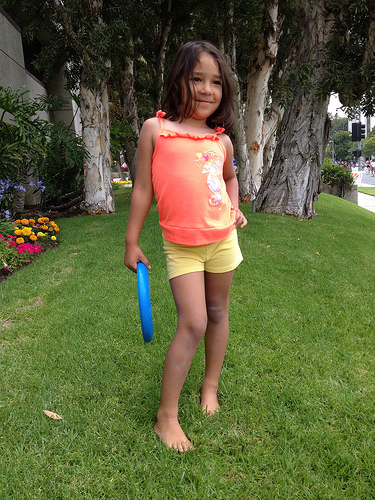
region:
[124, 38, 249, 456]
a young girl in shorts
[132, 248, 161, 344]
a blue Frisbee in right hand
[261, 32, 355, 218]
gray and black tree trunk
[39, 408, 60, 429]
die leaf on the ground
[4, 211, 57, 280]
a bed of flowers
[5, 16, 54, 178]
a concrete building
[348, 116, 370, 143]
a stop light over the street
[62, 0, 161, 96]
brushy green tree limbs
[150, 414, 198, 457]
toes on a foot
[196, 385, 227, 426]
grass around foot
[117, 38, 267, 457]
little girl posing for photo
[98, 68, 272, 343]
little girl holding a blue frisbee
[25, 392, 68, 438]
one leave on top of green grass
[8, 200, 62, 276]
pink and yellow flowers in a flower bed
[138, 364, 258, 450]
little girl wearing no shoes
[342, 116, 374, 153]
black stree light in the distance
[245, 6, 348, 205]
large tree trunk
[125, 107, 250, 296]
little girl wearing yellow shorts and an orange tank top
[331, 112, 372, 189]
street corner in the distance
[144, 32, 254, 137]
little girl with messy brown hair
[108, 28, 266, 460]
little girl is smiling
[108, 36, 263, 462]
girl holds a Frisbee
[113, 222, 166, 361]
a blue Frisbee on hand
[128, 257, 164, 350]
Frisbee is blue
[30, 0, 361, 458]
trees behind a girl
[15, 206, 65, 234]
flowers are orange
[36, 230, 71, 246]
flowers are yellow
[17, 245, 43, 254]
flowers are pink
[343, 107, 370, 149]
a traffic light in the street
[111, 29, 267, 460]
little girl wears yellow shorts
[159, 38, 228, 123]
the head of a girl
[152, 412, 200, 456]
the foot of a girl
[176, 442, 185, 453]
the toe of a girl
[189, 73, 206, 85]
the eye of a girl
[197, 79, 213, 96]
the nose of a girl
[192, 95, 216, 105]
the mouth of a girl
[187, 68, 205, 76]
the eyebrow of a girl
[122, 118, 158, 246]
the arm of a girl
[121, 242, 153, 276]
the hand of a girl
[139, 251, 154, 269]
the thumb of a girl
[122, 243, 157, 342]
the blue frisbee in her hand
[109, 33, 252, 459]
a girl posing for the picture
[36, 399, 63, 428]
a leaf on the grass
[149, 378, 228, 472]
a girls feet in the grass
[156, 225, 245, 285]
the girls yellow pair of shorts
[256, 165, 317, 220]
the large turnk of the tree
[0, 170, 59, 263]
flowers in the mulch by the wall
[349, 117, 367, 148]
the street light on the post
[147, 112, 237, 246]
the pink tank top on the girl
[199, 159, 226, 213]
a sea horse on the small girls shirt